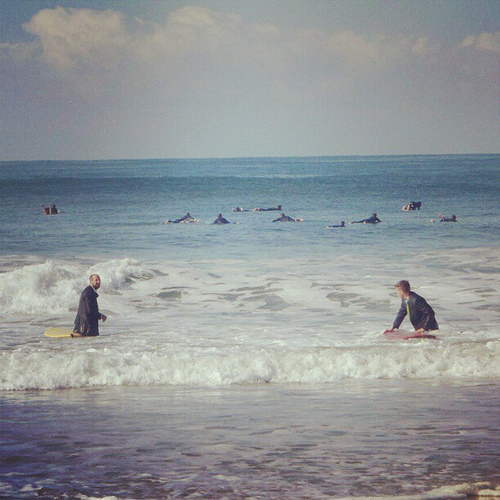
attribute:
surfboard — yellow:
[33, 325, 81, 343]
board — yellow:
[37, 321, 80, 343]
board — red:
[376, 325, 442, 345]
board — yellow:
[33, 321, 113, 343]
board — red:
[386, 331, 432, 342]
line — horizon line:
[4, 154, 230, 166]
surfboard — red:
[385, 329, 436, 345]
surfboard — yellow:
[43, 325, 76, 342]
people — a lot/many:
[42, 198, 473, 241]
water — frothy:
[249, 337, 330, 381]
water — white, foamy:
[149, 261, 305, 376]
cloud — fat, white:
[30, 5, 137, 77]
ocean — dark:
[0, 161, 494, 497]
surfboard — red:
[381, 325, 443, 347]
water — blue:
[0, 155, 496, 238]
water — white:
[0, 333, 488, 399]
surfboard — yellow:
[35, 318, 65, 360]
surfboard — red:
[384, 324, 434, 359]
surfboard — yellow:
[27, 319, 83, 364]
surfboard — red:
[370, 328, 446, 358]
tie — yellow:
[386, 294, 424, 336]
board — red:
[367, 311, 433, 356]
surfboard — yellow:
[24, 316, 71, 379]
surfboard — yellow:
[42, 314, 72, 359]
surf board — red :
[378, 329, 436, 339]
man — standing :
[75, 273, 107, 337]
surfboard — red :
[378, 329, 438, 342]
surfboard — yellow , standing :
[43, 325, 79, 338]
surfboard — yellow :
[44, 328, 84, 341]